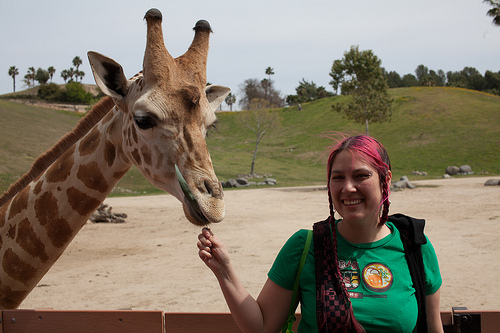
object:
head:
[85, 7, 232, 228]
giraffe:
[0, 7, 232, 310]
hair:
[323, 134, 392, 332]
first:
[171, 165, 202, 220]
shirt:
[267, 218, 442, 332]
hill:
[0, 95, 328, 199]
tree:
[326, 44, 394, 137]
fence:
[0, 307, 499, 333]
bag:
[311, 216, 362, 333]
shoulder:
[289, 218, 347, 249]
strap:
[284, 229, 315, 333]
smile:
[340, 196, 367, 207]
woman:
[197, 129, 445, 332]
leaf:
[172, 163, 210, 221]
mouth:
[180, 191, 227, 226]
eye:
[133, 111, 157, 132]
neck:
[0, 97, 133, 309]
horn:
[143, 7, 176, 76]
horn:
[175, 18, 211, 84]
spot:
[75, 158, 111, 193]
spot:
[44, 142, 77, 183]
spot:
[78, 124, 103, 157]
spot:
[65, 184, 102, 216]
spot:
[33, 191, 59, 222]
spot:
[7, 217, 49, 264]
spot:
[1, 246, 38, 287]